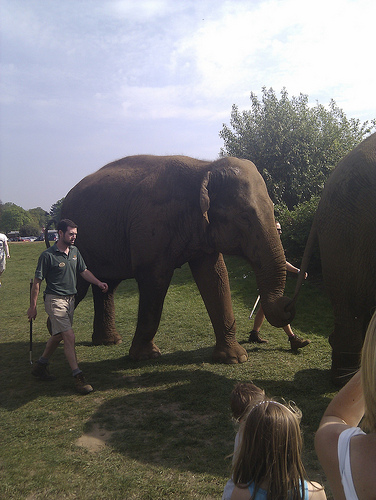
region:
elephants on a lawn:
[52, 130, 373, 366]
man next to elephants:
[14, 215, 117, 389]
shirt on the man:
[27, 243, 91, 291]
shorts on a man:
[38, 291, 80, 328]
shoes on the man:
[28, 368, 91, 385]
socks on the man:
[34, 357, 87, 375]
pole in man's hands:
[19, 270, 45, 368]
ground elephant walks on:
[10, 367, 344, 488]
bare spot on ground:
[73, 425, 110, 446]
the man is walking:
[20, 205, 104, 423]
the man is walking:
[7, 198, 117, 424]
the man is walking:
[23, 205, 119, 413]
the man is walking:
[20, 207, 136, 422]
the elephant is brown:
[48, 142, 295, 387]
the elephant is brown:
[46, 141, 297, 378]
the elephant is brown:
[41, 121, 313, 410]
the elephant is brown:
[31, 141, 301, 390]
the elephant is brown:
[30, 130, 304, 391]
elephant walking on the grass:
[42, 149, 304, 379]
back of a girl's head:
[221, 397, 327, 498]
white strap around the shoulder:
[332, 414, 369, 497]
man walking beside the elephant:
[16, 127, 299, 399]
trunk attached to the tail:
[240, 272, 307, 338]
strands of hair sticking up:
[270, 392, 308, 422]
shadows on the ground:
[0, 330, 367, 492]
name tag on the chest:
[55, 260, 67, 270]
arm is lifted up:
[317, 366, 372, 499]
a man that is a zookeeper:
[16, 216, 121, 396]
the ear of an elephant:
[188, 176, 224, 223]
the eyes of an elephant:
[221, 195, 285, 232]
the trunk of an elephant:
[243, 241, 299, 315]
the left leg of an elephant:
[185, 249, 253, 370]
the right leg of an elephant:
[136, 245, 166, 357]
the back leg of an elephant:
[82, 269, 123, 344]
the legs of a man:
[48, 277, 85, 368]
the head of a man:
[58, 220, 87, 252]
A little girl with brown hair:
[234, 404, 311, 495]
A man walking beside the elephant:
[26, 223, 107, 390]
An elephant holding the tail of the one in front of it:
[252, 227, 320, 327]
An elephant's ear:
[194, 172, 226, 219]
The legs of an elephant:
[70, 252, 242, 365]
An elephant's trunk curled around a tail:
[249, 248, 294, 323]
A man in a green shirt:
[36, 222, 85, 296]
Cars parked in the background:
[9, 230, 56, 242]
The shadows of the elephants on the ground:
[14, 327, 351, 493]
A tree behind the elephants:
[217, 88, 367, 230]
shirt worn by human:
[35, 243, 86, 294]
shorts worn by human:
[42, 289, 74, 331]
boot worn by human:
[31, 357, 51, 381]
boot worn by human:
[68, 369, 94, 395]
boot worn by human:
[247, 325, 265, 344]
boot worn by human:
[289, 333, 309, 350]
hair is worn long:
[228, 396, 306, 499]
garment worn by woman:
[335, 425, 364, 498]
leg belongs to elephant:
[194, 246, 248, 365]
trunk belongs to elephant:
[247, 220, 295, 327]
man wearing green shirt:
[23, 217, 135, 401]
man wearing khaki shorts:
[28, 214, 115, 402]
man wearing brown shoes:
[28, 220, 99, 399]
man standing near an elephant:
[24, 218, 111, 397]